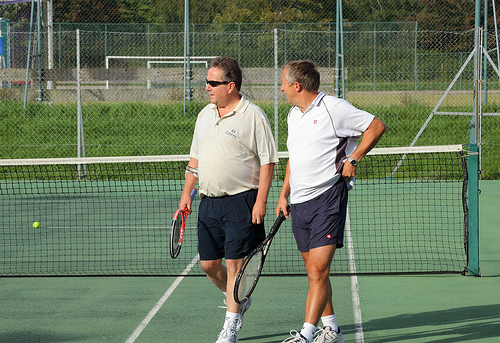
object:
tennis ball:
[33, 221, 40, 228]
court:
[2, 1, 500, 343]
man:
[179, 56, 280, 342]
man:
[274, 60, 387, 342]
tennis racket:
[170, 187, 198, 259]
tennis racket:
[233, 204, 291, 304]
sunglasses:
[206, 79, 229, 87]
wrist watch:
[347, 156, 359, 167]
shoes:
[215, 309, 243, 342]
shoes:
[283, 327, 313, 342]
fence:
[1, 28, 483, 181]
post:
[273, 28, 279, 180]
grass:
[0, 81, 499, 182]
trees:
[0, 1, 499, 69]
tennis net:
[1, 144, 470, 278]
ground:
[0, 179, 499, 343]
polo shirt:
[286, 92, 377, 206]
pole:
[75, 29, 83, 180]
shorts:
[197, 189, 266, 261]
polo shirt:
[188, 91, 280, 200]